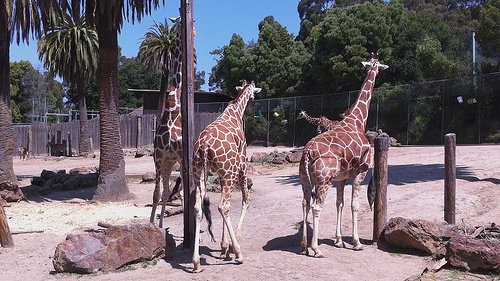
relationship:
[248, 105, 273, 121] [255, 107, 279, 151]
street sign on pole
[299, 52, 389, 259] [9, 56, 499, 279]
giraffe are in cage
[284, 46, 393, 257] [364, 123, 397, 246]
giraffe by post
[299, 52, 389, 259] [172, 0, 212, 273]
giraffe are by pole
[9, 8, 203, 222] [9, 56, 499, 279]
palm trees are in cage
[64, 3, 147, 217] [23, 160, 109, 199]
palm tree casting a shadow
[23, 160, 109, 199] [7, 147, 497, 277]
shadow on ground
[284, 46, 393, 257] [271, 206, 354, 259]
giraffe casting a shadow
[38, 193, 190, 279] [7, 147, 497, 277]
rock on ground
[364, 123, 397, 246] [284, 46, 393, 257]
post by giraffe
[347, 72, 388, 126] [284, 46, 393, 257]
neck on giraffe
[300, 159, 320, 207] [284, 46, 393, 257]
tail on giraffe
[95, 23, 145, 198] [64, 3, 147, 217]
trunk on palm tree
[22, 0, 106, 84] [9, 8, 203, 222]
leaves are on palm trees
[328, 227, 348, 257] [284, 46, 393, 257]
hoof on giraffe